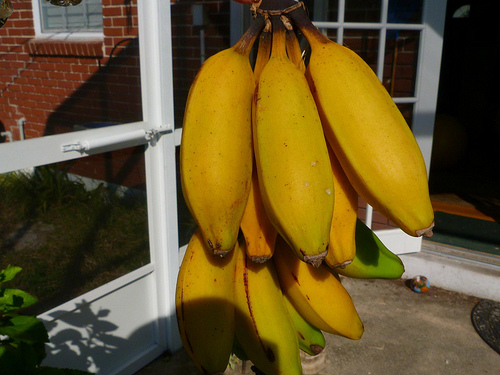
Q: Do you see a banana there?
A: Yes, there are bananas.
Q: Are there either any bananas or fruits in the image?
A: Yes, there are bananas.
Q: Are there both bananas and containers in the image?
A: No, there are bananas but no containers.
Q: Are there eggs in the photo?
A: No, there are no eggs.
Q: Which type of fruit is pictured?
A: The fruit is bananas.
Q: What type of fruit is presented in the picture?
A: The fruit is bananas.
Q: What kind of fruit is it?
A: The fruits are bananas.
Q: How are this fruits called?
A: Those are bananas.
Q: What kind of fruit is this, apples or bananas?
A: Those are bananas.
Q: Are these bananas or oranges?
A: These are bananas.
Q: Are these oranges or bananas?
A: These are bananas.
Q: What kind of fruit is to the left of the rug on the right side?
A: The fruits are bananas.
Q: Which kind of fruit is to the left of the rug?
A: The fruits are bananas.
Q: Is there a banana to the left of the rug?
A: Yes, there are bananas to the left of the rug.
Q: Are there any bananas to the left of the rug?
A: Yes, there are bananas to the left of the rug.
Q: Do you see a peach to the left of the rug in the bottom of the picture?
A: No, there are bananas to the left of the rug.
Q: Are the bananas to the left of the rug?
A: Yes, the bananas are to the left of the rug.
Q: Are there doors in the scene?
A: Yes, there is a door.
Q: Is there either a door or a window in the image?
A: Yes, there is a door.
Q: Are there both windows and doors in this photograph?
A: Yes, there are both a door and a window.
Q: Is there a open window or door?
A: Yes, there is an open door.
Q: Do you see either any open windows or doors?
A: Yes, there is an open door.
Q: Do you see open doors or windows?
A: Yes, there is an open door.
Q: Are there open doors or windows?
A: Yes, there is an open door.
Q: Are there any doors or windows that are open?
A: Yes, the door is open.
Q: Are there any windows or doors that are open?
A: Yes, the door is open.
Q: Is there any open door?
A: Yes, there is an open door.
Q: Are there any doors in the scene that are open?
A: Yes, there is a door that is open.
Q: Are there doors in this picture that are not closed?
A: Yes, there is a open door.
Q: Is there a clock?
A: No, there are no clocks.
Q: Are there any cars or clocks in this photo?
A: No, there are no clocks or cars.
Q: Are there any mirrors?
A: No, there are no mirrors.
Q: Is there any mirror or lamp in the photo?
A: No, there are no mirrors or lamps.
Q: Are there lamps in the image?
A: No, there are no lamps.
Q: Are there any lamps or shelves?
A: No, there are no lamps or shelves.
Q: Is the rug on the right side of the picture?
A: Yes, the rug is on the right of the image.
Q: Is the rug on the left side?
A: No, the rug is on the right of the image.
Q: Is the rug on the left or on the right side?
A: The rug is on the right of the image.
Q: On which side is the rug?
A: The rug is on the right of the image.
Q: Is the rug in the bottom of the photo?
A: Yes, the rug is in the bottom of the image.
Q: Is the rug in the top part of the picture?
A: No, the rug is in the bottom of the image.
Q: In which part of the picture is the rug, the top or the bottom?
A: The rug is in the bottom of the image.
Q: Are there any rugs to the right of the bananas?
A: Yes, there is a rug to the right of the bananas.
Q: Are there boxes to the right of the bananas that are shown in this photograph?
A: No, there is a rug to the right of the bananas.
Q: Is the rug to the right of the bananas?
A: Yes, the rug is to the right of the bananas.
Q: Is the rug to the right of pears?
A: No, the rug is to the right of the bananas.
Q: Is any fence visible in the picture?
A: No, there are no fences.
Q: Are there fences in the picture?
A: No, there are no fences.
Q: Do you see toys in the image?
A: Yes, there is a toy.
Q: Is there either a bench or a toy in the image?
A: Yes, there is a toy.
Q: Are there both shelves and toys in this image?
A: No, there is a toy but no shelves.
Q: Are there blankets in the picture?
A: No, there are no blankets.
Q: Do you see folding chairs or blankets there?
A: No, there are no blankets or folding chairs.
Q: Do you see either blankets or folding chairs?
A: No, there are no blankets or folding chairs.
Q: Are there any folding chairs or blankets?
A: No, there are no blankets or folding chairs.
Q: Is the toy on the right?
A: Yes, the toy is on the right of the image.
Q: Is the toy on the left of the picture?
A: No, the toy is on the right of the image.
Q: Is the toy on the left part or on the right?
A: The toy is on the right of the image.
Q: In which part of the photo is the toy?
A: The toy is on the right of the image.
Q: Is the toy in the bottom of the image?
A: Yes, the toy is in the bottom of the image.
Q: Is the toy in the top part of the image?
A: No, the toy is in the bottom of the image.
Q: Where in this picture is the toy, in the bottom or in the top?
A: The toy is in the bottom of the image.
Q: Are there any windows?
A: Yes, there is a window.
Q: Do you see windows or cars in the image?
A: Yes, there is a window.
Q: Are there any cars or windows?
A: Yes, there is a window.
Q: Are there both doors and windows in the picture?
A: Yes, there are both a window and doors.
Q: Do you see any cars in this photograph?
A: No, there are no cars.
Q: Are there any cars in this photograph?
A: No, there are no cars.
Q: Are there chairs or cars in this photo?
A: No, there are no cars or chairs.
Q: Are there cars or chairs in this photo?
A: No, there are no cars or chairs.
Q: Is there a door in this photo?
A: Yes, there is a door.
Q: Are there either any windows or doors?
A: Yes, there is a door.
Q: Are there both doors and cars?
A: No, there is a door but no cars.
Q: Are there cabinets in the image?
A: No, there are no cabinets.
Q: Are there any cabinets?
A: No, there are no cabinets.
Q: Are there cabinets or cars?
A: No, there are no cabinets or cars.